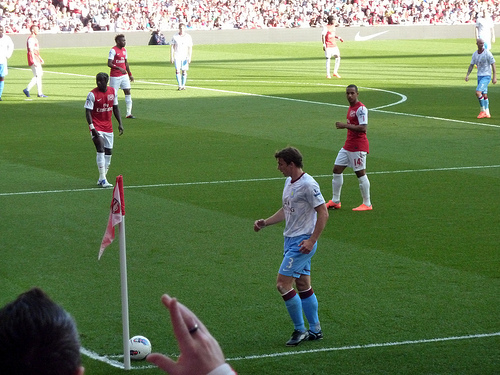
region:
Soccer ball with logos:
[126, 333, 151, 363]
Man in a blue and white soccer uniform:
[253, 143, 330, 348]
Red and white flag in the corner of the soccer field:
[96, 176, 133, 367]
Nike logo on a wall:
[348, 26, 402, 43]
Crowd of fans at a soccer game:
[0, 1, 498, 27]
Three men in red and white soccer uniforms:
[20, 23, 134, 189]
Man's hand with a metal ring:
[143, 293, 239, 373]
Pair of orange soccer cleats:
[325, 195, 378, 212]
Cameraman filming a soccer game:
[146, 28, 168, 45]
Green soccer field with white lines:
[0, 47, 499, 372]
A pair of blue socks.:
[274, 286, 321, 335]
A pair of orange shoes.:
[324, 197, 373, 211]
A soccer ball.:
[128, 334, 151, 361]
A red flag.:
[95, 173, 130, 263]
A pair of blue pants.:
[276, 232, 320, 277]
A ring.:
[185, 320, 200, 335]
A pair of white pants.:
[331, 146, 367, 171]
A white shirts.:
[281, 172, 325, 234]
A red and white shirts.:
[339, 100, 371, 155]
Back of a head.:
[7, 287, 79, 372]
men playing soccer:
[35, 17, 483, 352]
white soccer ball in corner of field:
[117, 325, 159, 366]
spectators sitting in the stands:
[42, 0, 293, 34]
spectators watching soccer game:
[200, 3, 337, 32]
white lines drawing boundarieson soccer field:
[135, 161, 238, 207]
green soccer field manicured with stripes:
[157, 62, 254, 249]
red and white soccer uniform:
[326, 72, 381, 208]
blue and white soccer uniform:
[265, 135, 326, 345]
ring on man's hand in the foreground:
[174, 308, 215, 351]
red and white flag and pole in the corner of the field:
[100, 167, 137, 372]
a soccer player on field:
[252, 146, 329, 348]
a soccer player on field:
[325, 85, 372, 210]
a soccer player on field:
[465, 39, 497, 119]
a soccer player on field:
[318, 13, 345, 79]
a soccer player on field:
[168, 22, 193, 89]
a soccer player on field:
[107, 33, 135, 120]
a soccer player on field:
[82, 71, 122, 188]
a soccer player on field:
[21, 22, 46, 97]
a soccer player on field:
[0, 21, 15, 102]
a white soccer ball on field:
[125, 334, 150, 361]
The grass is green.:
[0, 35, 498, 372]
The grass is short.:
[1, 37, 498, 374]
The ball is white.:
[126, 334, 153, 362]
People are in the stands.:
[0, 0, 499, 34]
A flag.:
[96, 171, 135, 265]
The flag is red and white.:
[95, 175, 130, 262]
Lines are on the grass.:
[0, 37, 498, 372]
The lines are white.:
[0, 36, 499, 373]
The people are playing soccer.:
[0, 9, 498, 354]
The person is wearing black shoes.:
[283, 325, 325, 345]